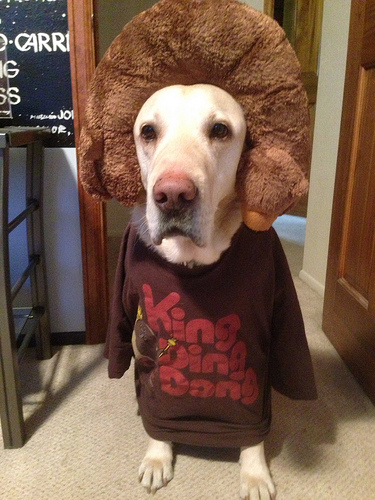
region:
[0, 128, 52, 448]
legs on a table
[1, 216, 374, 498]
white carpet on floor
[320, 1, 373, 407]
wooden interior door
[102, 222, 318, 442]
brown shirt with red writing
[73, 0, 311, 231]
object on dog's head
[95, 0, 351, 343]
an opening in a doorway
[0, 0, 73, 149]
blue sign with white writing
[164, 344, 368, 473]
dog's shadow on carpet floor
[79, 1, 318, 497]
white dog wearing a costume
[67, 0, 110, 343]
wood frame around door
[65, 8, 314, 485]
the dog is in costume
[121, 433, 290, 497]
the paws are white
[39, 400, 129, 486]
the floor is carpeted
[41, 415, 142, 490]
the floor is beige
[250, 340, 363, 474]
a shadow is on the floor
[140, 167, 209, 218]
the nose is pink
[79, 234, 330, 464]
the shirt is brown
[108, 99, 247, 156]
the eyes are open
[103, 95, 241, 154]
the eyes are brown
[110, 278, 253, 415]
the writing on the shirt is red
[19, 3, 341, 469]
dog in a costume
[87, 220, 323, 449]
shirt on the dog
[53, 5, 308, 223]
head piece on dog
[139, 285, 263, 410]
lettering on the shirt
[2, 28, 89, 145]
board behind the dog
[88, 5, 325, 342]
doorway to the room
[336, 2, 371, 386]
door to the room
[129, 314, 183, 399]
creature on the shirt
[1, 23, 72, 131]
lettering on the board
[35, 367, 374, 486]
carpet on the floor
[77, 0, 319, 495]
dog dressed in human clothes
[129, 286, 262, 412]
text on the dog's shirt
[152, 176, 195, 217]
the dog has a brown nose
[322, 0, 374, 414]
brown door in a room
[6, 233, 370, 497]
tan carpet on the ground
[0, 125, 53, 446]
metal rack on the ground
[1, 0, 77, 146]
blue sign with white lettering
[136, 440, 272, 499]
front paws of the dog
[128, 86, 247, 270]
the dog has white colored fur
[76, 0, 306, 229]
stuffed animal neck rest on the dog's head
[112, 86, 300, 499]
tan dog in clothing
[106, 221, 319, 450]
brown cotton tee shirt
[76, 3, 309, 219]
brown fur hat on dog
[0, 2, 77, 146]
blue poster on wall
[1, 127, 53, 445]
brown plastic desk on floor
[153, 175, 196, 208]
pink nose on dog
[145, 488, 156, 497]
white nails on dog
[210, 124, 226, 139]
brown eyes on dog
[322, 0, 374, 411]
brown stained wooden door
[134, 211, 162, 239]
white whiskers on dog